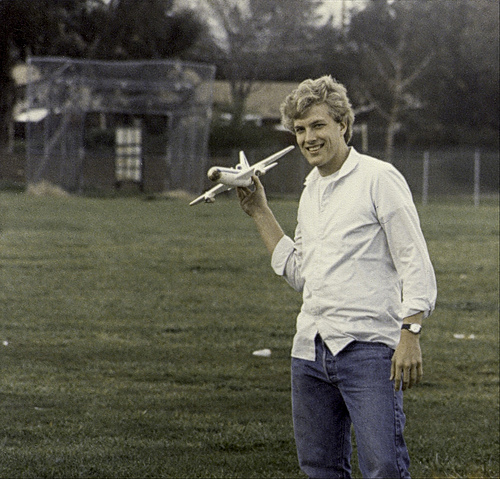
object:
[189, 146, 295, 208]
airplane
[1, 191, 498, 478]
grass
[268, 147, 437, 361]
shirt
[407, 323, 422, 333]
watch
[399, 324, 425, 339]
wrist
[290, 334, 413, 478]
pants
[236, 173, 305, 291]
arm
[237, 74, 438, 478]
man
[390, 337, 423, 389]
hand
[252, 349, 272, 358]
trash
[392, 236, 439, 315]
sleeves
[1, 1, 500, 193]
trees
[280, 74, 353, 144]
hair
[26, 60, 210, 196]
building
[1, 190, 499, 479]
ground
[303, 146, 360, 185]
collar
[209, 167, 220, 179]
tip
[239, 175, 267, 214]
right hand